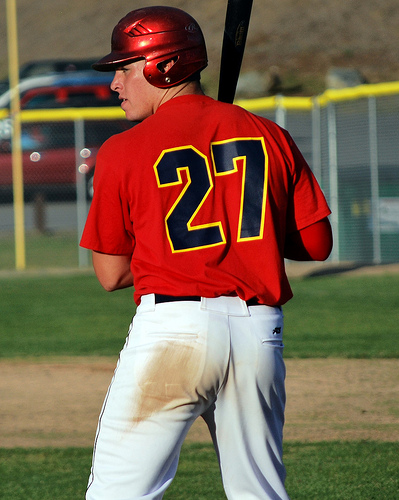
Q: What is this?
A: A baseball player.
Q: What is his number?
A: 27.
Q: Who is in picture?
A: An athlete.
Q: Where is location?
A: Baseball park.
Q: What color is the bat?
A: Black.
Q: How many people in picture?
A: One.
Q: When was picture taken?
A: During daylight.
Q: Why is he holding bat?
A: Ready to hit ball.